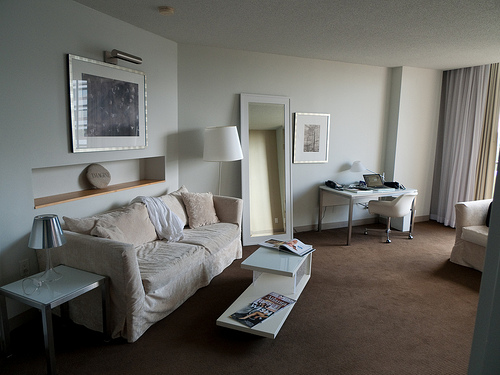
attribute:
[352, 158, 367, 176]
lamp shade — white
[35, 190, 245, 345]
sofa — long, beige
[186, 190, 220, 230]
pillow — beige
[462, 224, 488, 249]
cushion — cream-colored, fluffy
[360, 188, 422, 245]
chair — white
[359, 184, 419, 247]
chair — cream colored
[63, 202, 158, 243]
cushion — cream-colored, fluffy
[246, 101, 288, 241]
mirror — long, white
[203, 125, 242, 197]
lamp — silver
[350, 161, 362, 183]
lamp — silver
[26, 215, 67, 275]
lamp — silver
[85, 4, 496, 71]
ceiling — white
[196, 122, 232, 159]
lampshade — white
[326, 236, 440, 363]
carpet — brown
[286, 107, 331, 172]
frame — picture, wall